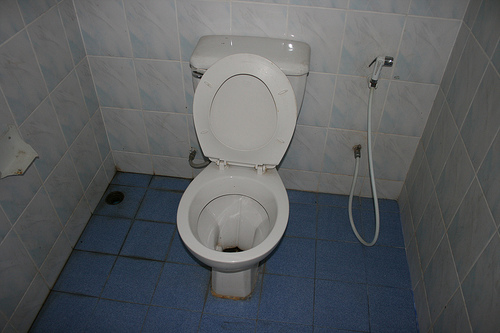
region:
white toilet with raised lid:
[176, 27, 318, 294]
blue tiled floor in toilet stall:
[39, 168, 428, 328]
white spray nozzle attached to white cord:
[347, 49, 399, 247]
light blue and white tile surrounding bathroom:
[4, 10, 498, 324]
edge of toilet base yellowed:
[211, 270, 261, 305]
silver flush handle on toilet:
[192, 70, 207, 79]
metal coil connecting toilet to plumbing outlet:
[181, 151, 208, 173]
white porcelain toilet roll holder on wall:
[3, 124, 40, 184]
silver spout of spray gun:
[383, 55, 397, 67]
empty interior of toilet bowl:
[198, 193, 270, 253]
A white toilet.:
[175, 33, 310, 300]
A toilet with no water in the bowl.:
[175, 34, 311, 298]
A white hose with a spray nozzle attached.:
[346, 55, 395, 247]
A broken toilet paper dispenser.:
[0, 123, 40, 182]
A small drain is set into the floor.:
[103, 187, 124, 207]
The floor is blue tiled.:
[24, 168, 419, 331]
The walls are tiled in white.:
[0, 0, 497, 332]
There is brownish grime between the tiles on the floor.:
[24, 169, 419, 331]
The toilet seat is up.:
[175, 33, 310, 300]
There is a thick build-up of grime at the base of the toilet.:
[175, 33, 311, 302]